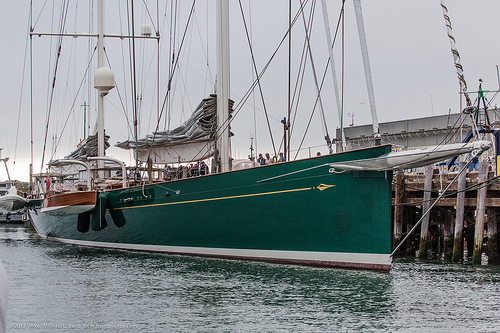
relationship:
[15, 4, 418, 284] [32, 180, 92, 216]
boat has a life boat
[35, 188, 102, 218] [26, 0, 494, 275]
lifeboat attached to boat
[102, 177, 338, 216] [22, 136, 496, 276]
arrow painted on side of boat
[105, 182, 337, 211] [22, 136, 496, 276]
arrow on side of boat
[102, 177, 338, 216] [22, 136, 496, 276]
arrow on side of boat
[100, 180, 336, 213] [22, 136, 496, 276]
stripe on boat